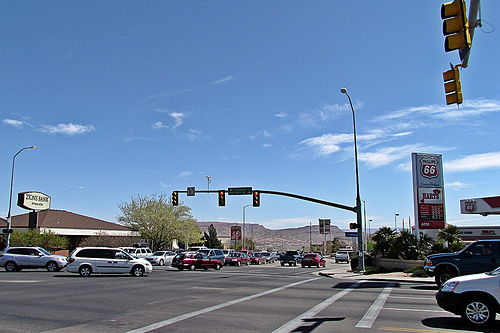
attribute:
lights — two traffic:
[422, 4, 478, 104]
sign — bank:
[17, 186, 57, 215]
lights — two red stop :
[209, 187, 264, 209]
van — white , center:
[70, 240, 153, 279]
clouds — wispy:
[150, 102, 394, 169]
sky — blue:
[14, 4, 255, 50]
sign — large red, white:
[399, 150, 450, 230]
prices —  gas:
[419, 190, 446, 228]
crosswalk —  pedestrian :
[349, 285, 420, 331]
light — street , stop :
[173, 178, 366, 250]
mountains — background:
[137, 200, 342, 242]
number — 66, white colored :
[422, 161, 441, 179]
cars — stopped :
[423, 234, 484, 323]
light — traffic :
[428, 7, 477, 105]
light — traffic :
[425, 0, 478, 103]